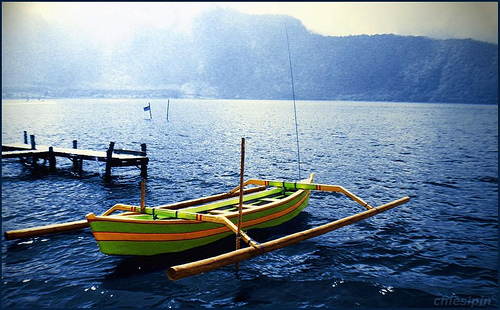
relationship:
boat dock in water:
[0, 136, 144, 186] [5, 104, 488, 270]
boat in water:
[102, 178, 343, 271] [5, 104, 488, 270]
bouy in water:
[140, 98, 153, 121] [5, 104, 488, 270]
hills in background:
[0, 2, 499, 105] [1, 4, 499, 93]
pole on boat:
[240, 139, 244, 237] [102, 178, 343, 271]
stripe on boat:
[106, 223, 296, 227] [102, 178, 343, 271]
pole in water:
[160, 94, 183, 127] [5, 104, 488, 270]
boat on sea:
[102, 178, 343, 271] [31, 96, 498, 253]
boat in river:
[85, 173, 410, 281] [24, 96, 422, 268]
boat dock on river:
[0, 130, 149, 188] [24, 96, 422, 268]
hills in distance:
[35, 28, 487, 100] [16, 12, 463, 84]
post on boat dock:
[97, 150, 117, 182] [0, 130, 149, 188]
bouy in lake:
[140, 98, 153, 121] [14, 102, 456, 269]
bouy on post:
[140, 98, 153, 121] [140, 101, 160, 131]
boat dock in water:
[0, 130, 149, 188] [5, 104, 488, 270]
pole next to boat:
[240, 139, 244, 237] [102, 178, 343, 271]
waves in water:
[442, 155, 463, 203] [5, 104, 488, 270]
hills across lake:
[0, 2, 499, 105] [14, 102, 456, 269]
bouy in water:
[146, 98, 159, 121] [5, 104, 488, 270]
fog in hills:
[71, 9, 216, 79] [0, 2, 499, 105]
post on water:
[97, 150, 117, 182] [5, 104, 488, 270]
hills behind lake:
[0, 2, 499, 105] [14, 102, 456, 269]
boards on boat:
[212, 195, 276, 212] [102, 178, 343, 271]